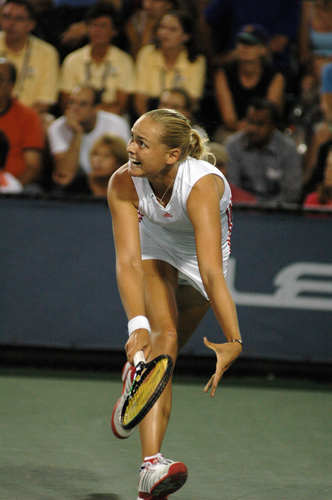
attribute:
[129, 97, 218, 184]
hair — blonde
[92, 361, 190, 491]
shoes — white, athletic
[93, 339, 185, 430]
racket — black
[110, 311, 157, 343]
wristband — white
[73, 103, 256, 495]
woman — playing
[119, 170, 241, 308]
clothes — white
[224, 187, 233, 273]
stripes — red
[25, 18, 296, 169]
audience — blurred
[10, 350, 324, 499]
court — tennis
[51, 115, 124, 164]
shirt — white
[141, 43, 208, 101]
shirt — yellow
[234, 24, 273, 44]
cap — blue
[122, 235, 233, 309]
dress — white